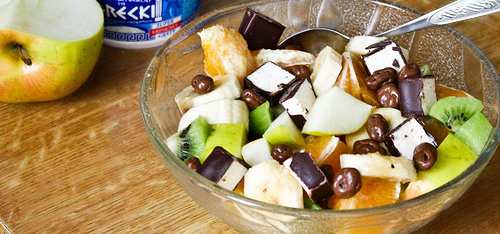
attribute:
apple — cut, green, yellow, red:
[0, 1, 103, 106]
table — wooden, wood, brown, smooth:
[1, 0, 497, 231]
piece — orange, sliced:
[198, 25, 257, 81]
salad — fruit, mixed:
[171, 17, 497, 211]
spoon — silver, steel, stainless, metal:
[282, 1, 499, 50]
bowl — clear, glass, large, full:
[136, 2, 500, 233]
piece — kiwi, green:
[167, 117, 207, 160]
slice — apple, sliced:
[304, 87, 374, 136]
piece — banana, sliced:
[242, 160, 304, 208]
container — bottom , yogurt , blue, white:
[99, 1, 199, 49]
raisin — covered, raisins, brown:
[190, 75, 215, 94]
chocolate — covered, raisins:
[413, 140, 439, 170]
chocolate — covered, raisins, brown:
[330, 166, 362, 200]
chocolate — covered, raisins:
[366, 69, 399, 87]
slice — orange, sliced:
[334, 176, 401, 208]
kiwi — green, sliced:
[432, 95, 484, 128]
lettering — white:
[104, 3, 155, 20]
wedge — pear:
[268, 109, 304, 146]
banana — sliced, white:
[312, 43, 344, 93]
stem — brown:
[15, 45, 34, 66]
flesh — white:
[1, 0, 104, 42]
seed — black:
[460, 113, 466, 120]